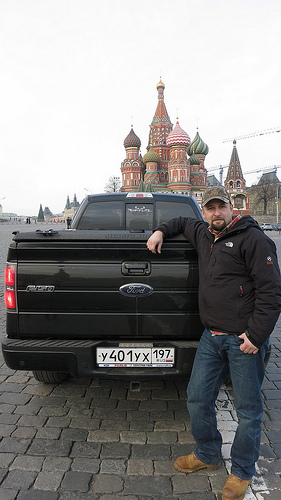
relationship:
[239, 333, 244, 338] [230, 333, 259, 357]
finger in pocket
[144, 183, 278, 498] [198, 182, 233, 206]
man in hat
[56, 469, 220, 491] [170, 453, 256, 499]
cobblestone beneath work boots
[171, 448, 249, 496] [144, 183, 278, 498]
boots on man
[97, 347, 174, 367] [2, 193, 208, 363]
plate on truck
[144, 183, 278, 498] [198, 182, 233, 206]
man wearing hat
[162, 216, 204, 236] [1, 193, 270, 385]
arm on truck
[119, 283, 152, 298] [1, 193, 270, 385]
logo on truck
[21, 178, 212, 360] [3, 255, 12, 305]
truck has red lights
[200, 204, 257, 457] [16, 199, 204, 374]
man leaning on truck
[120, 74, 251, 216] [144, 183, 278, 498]
building behind man